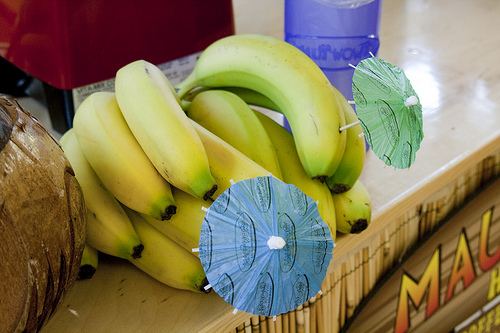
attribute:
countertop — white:
[2, 1, 499, 331]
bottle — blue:
[280, 0, 384, 162]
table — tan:
[399, 14, 491, 158]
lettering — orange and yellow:
[378, 202, 496, 332]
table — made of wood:
[393, 26, 475, 133]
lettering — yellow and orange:
[382, 220, 495, 332]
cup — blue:
[278, 3, 405, 105]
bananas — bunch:
[171, 31, 348, 186]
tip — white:
[394, 88, 426, 118]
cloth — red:
[1, 1, 235, 88]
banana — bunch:
[72, 92, 178, 222]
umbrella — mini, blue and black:
[193, 173, 332, 318]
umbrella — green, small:
[339, 54, 426, 173]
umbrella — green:
[338, 49, 434, 193]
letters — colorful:
[366, 218, 494, 305]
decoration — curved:
[3, 82, 80, 328]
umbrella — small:
[206, 206, 297, 291]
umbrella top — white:
[267, 230, 287, 254]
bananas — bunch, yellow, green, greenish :
[56, 32, 370, 297]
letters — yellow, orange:
[369, 223, 497, 308]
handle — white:
[335, 92, 422, 131]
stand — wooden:
[29, 2, 499, 327]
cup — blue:
[276, 1, 384, 158]